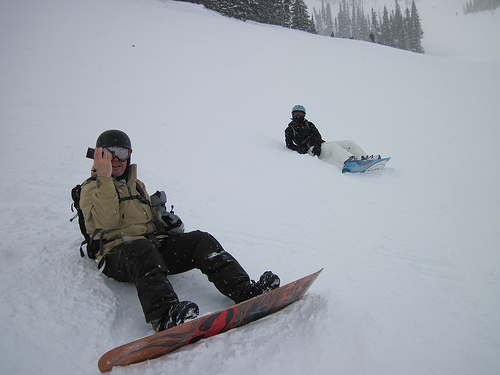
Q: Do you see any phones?
A: Yes, there is a phone.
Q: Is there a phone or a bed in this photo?
A: Yes, there is a phone.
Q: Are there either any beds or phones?
A: Yes, there is a phone.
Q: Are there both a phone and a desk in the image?
A: No, there is a phone but no desks.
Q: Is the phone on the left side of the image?
A: Yes, the phone is on the left of the image.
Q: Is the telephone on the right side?
A: No, the telephone is on the left of the image.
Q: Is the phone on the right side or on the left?
A: The phone is on the left of the image.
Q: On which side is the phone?
A: The phone is on the left of the image.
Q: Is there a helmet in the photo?
A: Yes, there is a helmet.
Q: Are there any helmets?
A: Yes, there is a helmet.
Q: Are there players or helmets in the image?
A: Yes, there is a helmet.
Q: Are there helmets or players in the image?
A: Yes, there is a helmet.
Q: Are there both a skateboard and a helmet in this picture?
A: No, there is a helmet but no skateboards.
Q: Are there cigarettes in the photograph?
A: No, there are no cigarettes.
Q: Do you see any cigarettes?
A: No, there are no cigarettes.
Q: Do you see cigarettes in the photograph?
A: No, there are no cigarettes.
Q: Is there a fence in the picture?
A: No, there are no fences.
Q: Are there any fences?
A: No, there are no fences.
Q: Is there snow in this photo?
A: Yes, there is snow.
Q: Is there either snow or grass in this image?
A: Yes, there is snow.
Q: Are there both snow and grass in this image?
A: No, there is snow but no grass.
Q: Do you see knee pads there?
A: No, there are no knee pads.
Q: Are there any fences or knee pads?
A: No, there are no knee pads or fences.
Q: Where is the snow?
A: The snow is on the ground.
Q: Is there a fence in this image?
A: No, there are no fences.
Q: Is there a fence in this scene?
A: No, there are no fences.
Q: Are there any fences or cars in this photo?
A: No, there are no fences or cars.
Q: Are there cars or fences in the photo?
A: No, there are no fences or cars.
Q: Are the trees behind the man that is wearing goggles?
A: Yes, the trees are behind the man.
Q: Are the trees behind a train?
A: No, the trees are behind the man.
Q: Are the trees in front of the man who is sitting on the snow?
A: No, the trees are behind the man.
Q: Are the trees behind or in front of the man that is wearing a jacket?
A: The trees are behind the man.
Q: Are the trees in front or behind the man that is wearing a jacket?
A: The trees are behind the man.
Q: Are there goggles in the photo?
A: Yes, there are goggles.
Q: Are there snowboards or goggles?
A: Yes, there are goggles.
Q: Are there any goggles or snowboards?
A: Yes, there are goggles.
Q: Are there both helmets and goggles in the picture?
A: Yes, there are both goggles and a helmet.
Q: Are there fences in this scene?
A: No, there are no fences.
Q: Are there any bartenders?
A: No, there are no bartenders.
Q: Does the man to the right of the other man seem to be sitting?
A: Yes, the man is sitting.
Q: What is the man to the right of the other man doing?
A: The man is sitting.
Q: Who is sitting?
A: The man is sitting.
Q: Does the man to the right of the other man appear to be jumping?
A: No, the man is sitting.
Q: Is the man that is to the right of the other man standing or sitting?
A: The man is sitting.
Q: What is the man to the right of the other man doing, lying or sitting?
A: The man is sitting.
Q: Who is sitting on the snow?
A: The man is sitting on the snow.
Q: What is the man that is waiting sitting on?
A: The man is sitting on the snow.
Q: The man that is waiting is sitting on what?
A: The man is sitting on the snow.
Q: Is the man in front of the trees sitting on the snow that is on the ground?
A: Yes, the man is sitting on the snow.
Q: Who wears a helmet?
A: The man wears a helmet.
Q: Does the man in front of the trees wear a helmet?
A: Yes, the man wears a helmet.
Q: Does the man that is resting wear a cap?
A: No, the man wears a helmet.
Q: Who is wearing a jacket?
A: The man is wearing a jacket.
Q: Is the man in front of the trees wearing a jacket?
A: Yes, the man is wearing a jacket.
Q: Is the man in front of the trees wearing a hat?
A: No, the man is wearing a jacket.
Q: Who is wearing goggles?
A: The man is wearing goggles.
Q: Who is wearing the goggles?
A: The man is wearing goggles.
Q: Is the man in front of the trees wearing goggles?
A: Yes, the man is wearing goggles.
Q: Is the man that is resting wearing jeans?
A: No, the man is wearing goggles.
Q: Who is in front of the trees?
A: The man is in front of the trees.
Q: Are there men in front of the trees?
A: Yes, there is a man in front of the trees.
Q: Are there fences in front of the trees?
A: No, there is a man in front of the trees.